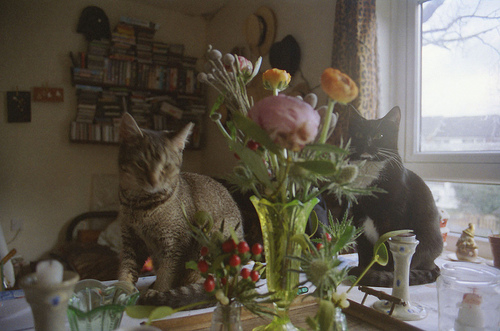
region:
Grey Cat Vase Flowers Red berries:
[73, 100, 340, 320]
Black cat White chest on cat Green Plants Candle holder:
[317, 89, 452, 290]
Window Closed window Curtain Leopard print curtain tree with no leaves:
[312, 0, 497, 175]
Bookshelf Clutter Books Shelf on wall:
[59, 1, 234, 162]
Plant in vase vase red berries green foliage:
[167, 204, 269, 326]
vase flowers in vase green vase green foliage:
[225, 179, 345, 311]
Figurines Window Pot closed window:
[382, 149, 497, 277]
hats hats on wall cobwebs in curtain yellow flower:
[193, 2, 320, 84]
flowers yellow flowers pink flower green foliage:
[187, 48, 397, 213]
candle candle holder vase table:
[0, 227, 161, 328]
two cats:
[97, 103, 460, 306]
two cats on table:
[59, 89, 466, 307]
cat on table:
[87, 100, 262, 323]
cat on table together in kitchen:
[312, 97, 473, 294]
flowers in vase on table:
[175, 51, 360, 327]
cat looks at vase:
[73, 40, 351, 326]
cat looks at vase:
[187, 50, 438, 322]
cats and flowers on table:
[65, 42, 451, 327]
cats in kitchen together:
[67, 42, 457, 307]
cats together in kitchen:
[70, 88, 457, 314]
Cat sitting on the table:
[92, 108, 255, 308]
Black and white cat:
[327, 96, 454, 283]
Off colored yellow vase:
[243, 187, 328, 329]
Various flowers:
[192, 31, 372, 205]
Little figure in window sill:
[449, 216, 484, 268]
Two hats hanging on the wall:
[228, 6, 325, 74]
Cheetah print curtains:
[322, 2, 389, 122]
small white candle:
[26, 246, 79, 290]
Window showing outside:
[382, 0, 498, 188]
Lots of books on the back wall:
[41, 4, 223, 151]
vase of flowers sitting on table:
[203, 49, 361, 329]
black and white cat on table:
[342, 100, 446, 285]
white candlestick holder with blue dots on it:
[374, 227, 430, 317]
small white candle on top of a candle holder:
[36, 246, 68, 287]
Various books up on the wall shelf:
[62, 35, 219, 154]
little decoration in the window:
[452, 221, 487, 258]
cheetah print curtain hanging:
[329, 2, 388, 122]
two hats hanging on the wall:
[237, 10, 322, 81]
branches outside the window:
[422, 0, 496, 57]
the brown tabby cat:
[102, 111, 247, 284]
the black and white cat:
[343, 101, 444, 285]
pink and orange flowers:
[247, 59, 361, 154]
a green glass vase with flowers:
[248, 61, 318, 329]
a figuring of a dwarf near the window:
[450, 216, 482, 266]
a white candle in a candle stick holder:
[17, 250, 74, 330]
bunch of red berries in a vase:
[193, 219, 265, 329]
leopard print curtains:
[330, 1, 385, 118]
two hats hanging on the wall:
[228, 3, 308, 73]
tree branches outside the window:
[420, 0, 498, 60]